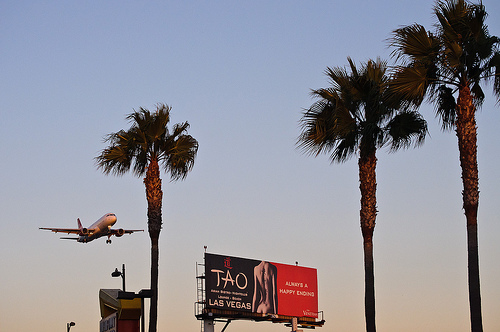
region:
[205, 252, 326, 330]
the sign has lettering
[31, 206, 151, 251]
the airplane is in the sky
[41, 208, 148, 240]
the airplane is flying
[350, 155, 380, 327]
the trunk is brown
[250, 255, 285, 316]
the person is naked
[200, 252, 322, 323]
the sign has a person's profile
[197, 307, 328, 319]
the billboard has a railing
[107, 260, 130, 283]
the streetlight is grey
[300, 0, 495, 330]
the palm trees has fronds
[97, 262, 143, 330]
the sign is beneath the street lamp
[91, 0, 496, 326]
three palm trees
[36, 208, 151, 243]
airplane flying low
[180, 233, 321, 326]
billboard for a place in Las Vegas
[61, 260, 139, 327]
lamp posts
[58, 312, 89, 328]
top of the lamp post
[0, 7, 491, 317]
blue sky at the top and orange at the bottom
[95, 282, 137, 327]
a yellow sign with lights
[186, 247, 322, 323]
a billboard that mentions the tao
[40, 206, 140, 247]
plane headed toward the trees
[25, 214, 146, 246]
large white commercial airplane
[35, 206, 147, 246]
An airplane in the air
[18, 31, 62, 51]
Part of the sky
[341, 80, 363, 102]
Part of the tree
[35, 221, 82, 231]
The right wing of the airplane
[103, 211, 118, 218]
A window on the airplane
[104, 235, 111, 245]
Part of the front wheels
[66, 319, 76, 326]
Part of the streetlight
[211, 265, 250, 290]
Letters on the sign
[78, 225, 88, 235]
The right engine of the airplane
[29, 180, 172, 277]
the plane is in the air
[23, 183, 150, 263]
the plane is flying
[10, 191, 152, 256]
the plane is landing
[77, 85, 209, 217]
the tree is blowing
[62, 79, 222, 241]
the palm tree is tall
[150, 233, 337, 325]
the billboard is black and red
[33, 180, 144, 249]
the plane is white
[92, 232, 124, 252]
the wheels are down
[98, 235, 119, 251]
the wheels are black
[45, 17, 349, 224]
the sky is blue and clear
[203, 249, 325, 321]
red and black billboard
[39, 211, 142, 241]
passenger airplane flying in sky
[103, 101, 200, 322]
tall palm tree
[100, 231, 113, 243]
landing gear on airplane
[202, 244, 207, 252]
light on top of billboard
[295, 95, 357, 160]
green palm leaves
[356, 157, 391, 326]
brown trunk of a palm tree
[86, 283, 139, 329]
side of a large sign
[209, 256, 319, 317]
advertisement for TAO Las Vegas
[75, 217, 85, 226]
tail of passenger airplane